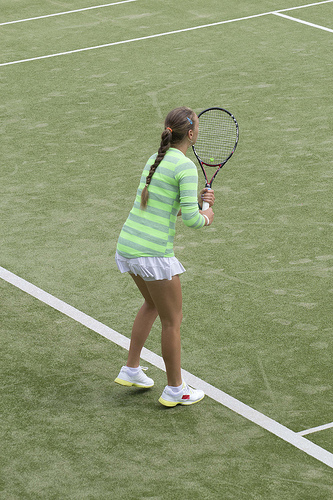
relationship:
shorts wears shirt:
[115, 253, 186, 282] [116, 146, 204, 258]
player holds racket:
[113, 105, 214, 406] [186, 100, 235, 217]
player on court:
[113, 105, 214, 406] [0, 2, 332, 496]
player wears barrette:
[113, 105, 214, 406] [183, 107, 195, 127]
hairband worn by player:
[162, 124, 174, 133] [113, 105, 214, 406]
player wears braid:
[104, 96, 236, 407] [127, 130, 191, 205]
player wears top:
[113, 105, 214, 406] [113, 146, 207, 263]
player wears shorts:
[113, 105, 214, 406] [115, 253, 186, 282]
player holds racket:
[113, 105, 214, 406] [186, 100, 242, 217]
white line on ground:
[20, 39, 219, 58] [12, 79, 134, 179]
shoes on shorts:
[156, 382, 274, 408] [115, 253, 186, 282]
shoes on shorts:
[156, 382, 209, 408] [115, 253, 186, 282]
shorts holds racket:
[115, 253, 186, 282] [186, 100, 242, 217]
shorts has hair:
[115, 253, 186, 282] [137, 101, 189, 206]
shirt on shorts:
[116, 146, 204, 258] [115, 253, 186, 282]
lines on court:
[5, 8, 197, 66] [0, 2, 332, 500]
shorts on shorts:
[135, 255, 177, 283] [115, 253, 186, 282]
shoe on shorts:
[112, 365, 156, 390] [115, 253, 186, 282]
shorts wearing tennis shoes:
[115, 253, 186, 282] [111, 355, 241, 410]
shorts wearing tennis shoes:
[115, 253, 186, 282] [111, 362, 206, 407]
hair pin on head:
[185, 114, 193, 126] [161, 101, 200, 149]